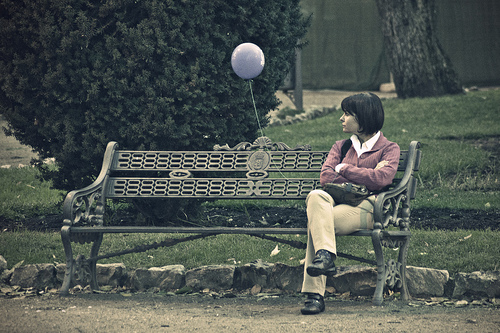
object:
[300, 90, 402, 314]
girl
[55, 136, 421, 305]
bench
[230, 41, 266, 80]
balloon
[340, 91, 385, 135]
hair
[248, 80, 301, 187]
string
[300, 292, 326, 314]
shoes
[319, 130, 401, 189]
blazer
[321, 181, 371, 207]
bag